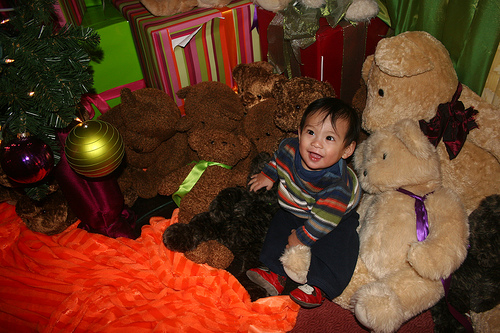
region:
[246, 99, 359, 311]
Little baby boy looking up.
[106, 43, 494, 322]
Lots of different teddy bears.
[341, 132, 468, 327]
Teddy bear with a purple ribbon.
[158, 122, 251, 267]
Brown teddy bear with a green ribbon.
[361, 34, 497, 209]
Light brown teddy bear with maroon bow.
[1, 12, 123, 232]
Christmas tree with decorations.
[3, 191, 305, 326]
Orange velour type blanket.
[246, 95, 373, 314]
Little red shoes on boy.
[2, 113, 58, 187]
Shiny purple round Christmas ball.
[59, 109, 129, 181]
Green Christmas ball decoration with stripes.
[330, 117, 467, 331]
Beige fuzzy teddy bear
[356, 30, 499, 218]
Beige fuzzy teddy bear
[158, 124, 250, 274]
Brown fuzzy teddy bear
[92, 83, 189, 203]
Beige fuzzy teddy bear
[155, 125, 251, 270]
Beige fuzzy teddy bear wearing green ribbon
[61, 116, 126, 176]
Round green ornament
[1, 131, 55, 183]
Round purple ornament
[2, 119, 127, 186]
Round purple ornament next to round green ornament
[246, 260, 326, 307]
Red shoes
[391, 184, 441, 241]
Purple ribbon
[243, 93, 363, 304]
a very small boy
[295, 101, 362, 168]
boy is looking up and smiling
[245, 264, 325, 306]
boy is wearing red shoes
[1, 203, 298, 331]
a very soft-looking orange striped blanket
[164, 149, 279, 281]
child's right hand resting on a dark teddy bear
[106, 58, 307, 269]
a group of dark brown teddy bears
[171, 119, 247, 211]
green ribbon tied around bear's neck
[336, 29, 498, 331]
two large, light brown bears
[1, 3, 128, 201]
large round ornaments on an artificial Christmas tree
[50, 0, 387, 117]
large wrapped boxes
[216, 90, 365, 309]
little boy sitting among teddy bears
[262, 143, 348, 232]
long sleeve striped shirt of little boy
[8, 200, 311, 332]
orange striped blanket on floor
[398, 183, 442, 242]
purple ribbon on teddy bear's neck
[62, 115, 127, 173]
large yellow green ornament on tree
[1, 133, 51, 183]
purple ornament hanging from tree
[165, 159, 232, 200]
green ribbon around bear's neck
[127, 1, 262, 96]
striped wrapping paper on figt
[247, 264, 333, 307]
red shoes of young child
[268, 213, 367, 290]
navy pants on young boy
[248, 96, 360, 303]
the baby on the stuffed animals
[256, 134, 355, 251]
the long sleeved sweater on the baby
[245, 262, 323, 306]
the shoes on the baby's feet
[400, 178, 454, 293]
the purple tie around the bear's neck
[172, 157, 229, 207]
the green tie around the bear's neck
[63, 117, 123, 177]
the large green ornament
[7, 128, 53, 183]
the large purple ornament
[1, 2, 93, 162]
the green christmas tree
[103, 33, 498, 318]
the pile of stuffed animals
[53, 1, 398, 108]
a group of wrapped boxes